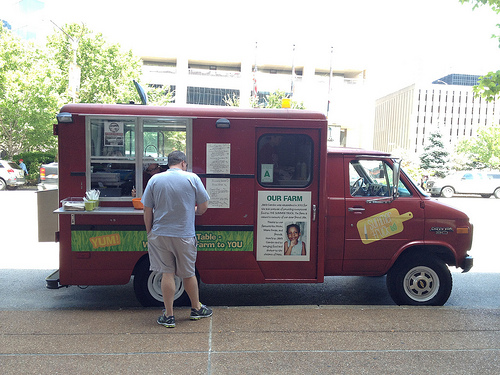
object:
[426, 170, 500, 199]
car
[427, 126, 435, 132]
wall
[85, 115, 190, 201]
window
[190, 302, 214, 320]
shoe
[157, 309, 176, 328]
shoes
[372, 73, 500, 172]
building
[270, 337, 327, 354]
ground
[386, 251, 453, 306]
wheel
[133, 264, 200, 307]
wheel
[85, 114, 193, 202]
grey frame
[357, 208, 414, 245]
sign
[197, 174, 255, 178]
handle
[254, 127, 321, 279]
door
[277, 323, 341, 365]
ground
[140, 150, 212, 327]
man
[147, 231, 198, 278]
pants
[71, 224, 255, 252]
green sign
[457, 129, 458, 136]
window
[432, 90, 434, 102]
window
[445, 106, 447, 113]
window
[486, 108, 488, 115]
window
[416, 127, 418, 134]
window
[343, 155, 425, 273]
door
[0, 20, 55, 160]
tree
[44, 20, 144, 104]
tree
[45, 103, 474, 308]
mobile kitchen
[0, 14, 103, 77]
sun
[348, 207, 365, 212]
handle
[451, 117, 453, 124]
window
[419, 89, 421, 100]
window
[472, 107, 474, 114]
window